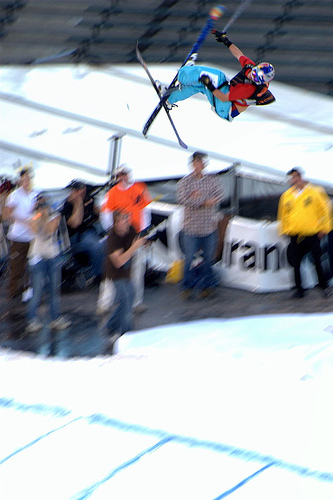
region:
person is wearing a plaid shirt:
[174, 174, 225, 235]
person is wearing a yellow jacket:
[280, 186, 331, 241]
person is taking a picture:
[34, 195, 58, 229]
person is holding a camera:
[34, 195, 50, 227]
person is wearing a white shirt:
[11, 185, 33, 248]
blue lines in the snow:
[90, 414, 218, 454]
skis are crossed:
[134, 17, 219, 144]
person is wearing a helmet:
[247, 56, 278, 96]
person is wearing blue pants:
[161, 63, 229, 117]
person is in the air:
[137, 60, 288, 128]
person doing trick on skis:
[23, 0, 319, 444]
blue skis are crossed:
[111, 9, 281, 164]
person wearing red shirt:
[215, 48, 282, 131]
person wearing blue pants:
[163, 50, 240, 120]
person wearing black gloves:
[199, 19, 239, 92]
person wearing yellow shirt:
[268, 176, 329, 244]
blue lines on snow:
[45, 394, 304, 490]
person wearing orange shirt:
[91, 171, 149, 231]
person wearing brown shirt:
[97, 227, 140, 285]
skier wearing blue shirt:
[237, 55, 280, 89]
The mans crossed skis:
[131, 50, 197, 157]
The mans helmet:
[253, 61, 276, 84]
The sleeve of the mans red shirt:
[229, 81, 252, 97]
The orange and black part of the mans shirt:
[230, 71, 275, 108]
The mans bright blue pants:
[163, 61, 226, 125]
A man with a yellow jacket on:
[283, 165, 331, 246]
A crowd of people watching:
[16, 163, 330, 315]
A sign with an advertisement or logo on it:
[110, 191, 330, 283]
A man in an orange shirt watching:
[101, 167, 148, 311]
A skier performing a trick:
[127, 52, 277, 158]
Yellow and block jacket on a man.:
[283, 195, 325, 215]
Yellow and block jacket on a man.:
[242, 464, 285, 481]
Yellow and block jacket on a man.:
[91, 183, 176, 216]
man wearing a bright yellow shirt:
[274, 167, 331, 302]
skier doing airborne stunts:
[127, 1, 280, 153]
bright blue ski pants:
[161, 58, 235, 123]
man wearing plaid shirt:
[168, 150, 223, 303]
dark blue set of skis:
[129, 2, 225, 154]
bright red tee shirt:
[226, 51, 262, 107]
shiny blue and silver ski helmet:
[247, 60, 275, 86]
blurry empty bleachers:
[1, 2, 330, 83]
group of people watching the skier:
[0, 146, 332, 336]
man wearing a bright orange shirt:
[97, 162, 153, 317]